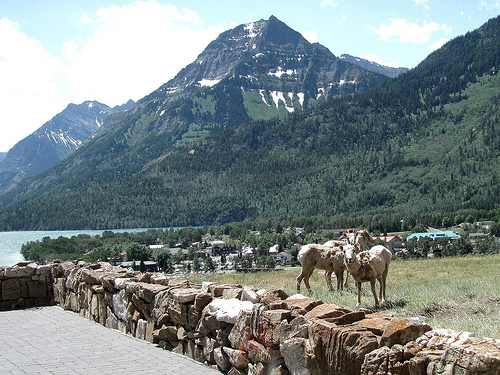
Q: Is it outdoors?
A: Yes, it is outdoors.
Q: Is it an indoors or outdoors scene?
A: It is outdoors.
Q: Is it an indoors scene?
A: No, it is outdoors.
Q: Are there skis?
A: No, there are no skis.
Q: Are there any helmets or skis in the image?
A: No, there are no skis or helmets.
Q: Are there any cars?
A: No, there are no cars.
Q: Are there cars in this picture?
A: No, there are no cars.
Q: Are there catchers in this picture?
A: No, there are no catchers.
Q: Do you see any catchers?
A: No, there are no catchers.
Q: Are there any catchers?
A: No, there are no catchers.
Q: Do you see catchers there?
A: No, there are no catchers.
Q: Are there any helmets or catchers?
A: No, there are no catchers or helmets.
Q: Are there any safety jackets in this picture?
A: No, there are no safety jackets.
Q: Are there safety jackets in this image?
A: No, there are no safety jackets.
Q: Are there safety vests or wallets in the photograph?
A: No, there are no safety vests or wallets.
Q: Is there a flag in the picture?
A: No, there are no flags.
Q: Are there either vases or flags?
A: No, there are no flags or vases.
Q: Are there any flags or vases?
A: No, there are no flags or vases.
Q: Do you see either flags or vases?
A: No, there are no flags or vases.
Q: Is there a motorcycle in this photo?
A: No, there are no motorcycles.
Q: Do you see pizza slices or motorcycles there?
A: No, there are no motorcycles or pizza slices.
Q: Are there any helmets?
A: No, there are no helmets.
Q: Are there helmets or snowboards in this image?
A: No, there are no helmets or snowboards.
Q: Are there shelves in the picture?
A: No, there are no shelves.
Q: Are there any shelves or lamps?
A: No, there are no shelves or lamps.